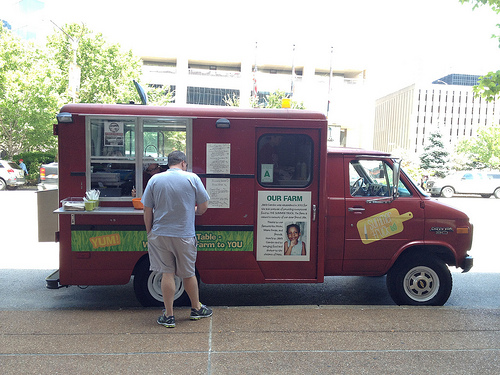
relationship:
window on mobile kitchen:
[85, 112, 190, 209] [31, 88, 482, 312]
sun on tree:
[0, 14, 152, 119] [44, 20, 144, 104]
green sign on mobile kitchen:
[59, 222, 261, 265] [45, 103, 474, 308]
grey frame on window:
[71, 110, 179, 223] [79, 113, 196, 212]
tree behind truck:
[2, 18, 55, 160] [46, 99, 477, 306]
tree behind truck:
[44, 20, 144, 104] [46, 99, 477, 306]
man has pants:
[134, 146, 216, 331] [140, 227, 200, 280]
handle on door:
[344, 201, 370, 214] [319, 154, 420, 284]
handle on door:
[200, 168, 261, 188] [242, 122, 323, 284]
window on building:
[448, 115, 456, 125] [364, 74, 484, 173]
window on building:
[415, 85, 422, 100] [407, 74, 498, 175]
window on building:
[417, 87, 422, 102] [367, 69, 499, 164]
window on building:
[431, 87, 436, 104] [367, 69, 499, 164]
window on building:
[441, 104, 450, 116] [367, 69, 499, 164]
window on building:
[483, 107, 488, 117] [367, 69, 499, 164]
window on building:
[413, 125, 420, 135] [367, 69, 499, 164]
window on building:
[468, 104, 478, 119] [415, 87, 490, 139]